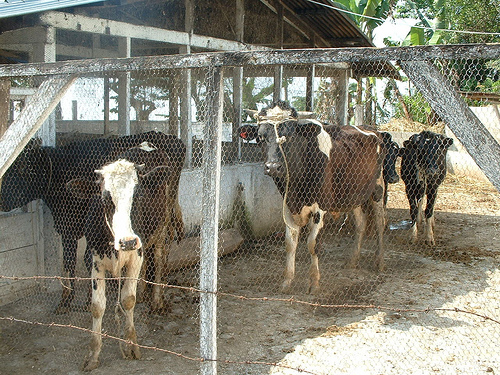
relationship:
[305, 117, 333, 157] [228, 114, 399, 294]
spot on cow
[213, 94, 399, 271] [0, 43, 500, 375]
cow in fence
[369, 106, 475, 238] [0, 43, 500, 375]
cow in fence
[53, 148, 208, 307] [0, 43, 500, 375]
cow in fence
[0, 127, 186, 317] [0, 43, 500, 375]
cow in fence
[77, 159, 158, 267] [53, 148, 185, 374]
head of cow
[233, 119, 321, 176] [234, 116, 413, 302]
head of cow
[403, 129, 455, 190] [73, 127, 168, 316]
head of cow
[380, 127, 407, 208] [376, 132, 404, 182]
cow has head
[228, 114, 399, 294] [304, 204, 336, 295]
cow has leg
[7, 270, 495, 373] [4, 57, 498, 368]
wire on fence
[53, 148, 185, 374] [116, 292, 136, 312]
cow has knee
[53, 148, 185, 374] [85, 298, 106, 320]
cow has knee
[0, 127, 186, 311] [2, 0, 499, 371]
cow in shed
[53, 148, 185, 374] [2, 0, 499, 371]
cow in shed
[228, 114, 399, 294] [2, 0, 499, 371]
cow in shed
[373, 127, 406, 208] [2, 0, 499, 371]
cow in shed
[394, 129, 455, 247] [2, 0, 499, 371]
cow in shed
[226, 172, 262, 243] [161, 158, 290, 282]
green water on wall